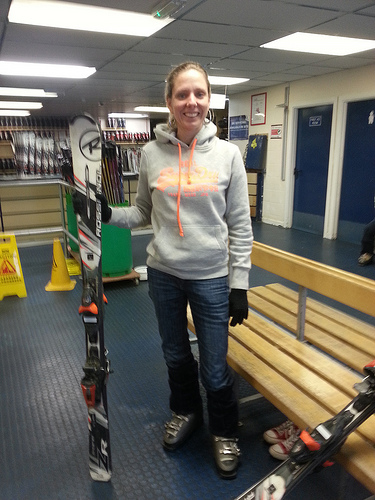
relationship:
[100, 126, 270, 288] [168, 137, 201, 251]
hoodie has tie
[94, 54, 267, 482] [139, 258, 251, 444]
women wears jeans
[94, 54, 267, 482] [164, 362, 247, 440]
women wears leg warmers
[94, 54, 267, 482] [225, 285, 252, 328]
women wears gloves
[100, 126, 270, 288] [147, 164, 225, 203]
hoodie has print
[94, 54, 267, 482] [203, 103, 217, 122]
women wears earrings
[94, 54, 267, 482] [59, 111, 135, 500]
women holds ski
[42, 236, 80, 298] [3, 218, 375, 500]
cone on floor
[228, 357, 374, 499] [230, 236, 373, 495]
ski on bench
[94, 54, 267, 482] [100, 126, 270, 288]
women wears hoodie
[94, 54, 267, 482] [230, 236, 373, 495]
women near bench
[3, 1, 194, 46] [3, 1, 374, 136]
lights on ceiling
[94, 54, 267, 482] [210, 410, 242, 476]
woman wears sneakers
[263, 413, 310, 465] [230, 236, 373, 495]
sneakers under bench